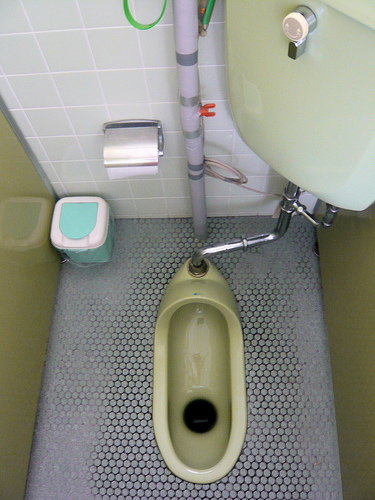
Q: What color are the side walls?
A: Green.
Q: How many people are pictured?
A: None.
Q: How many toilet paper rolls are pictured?
A: One.